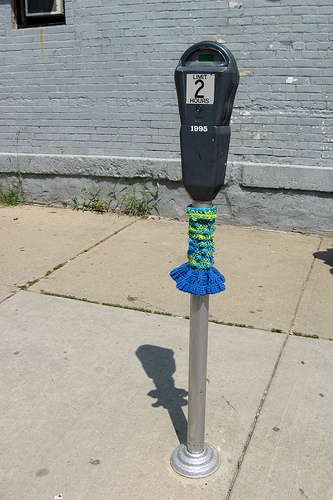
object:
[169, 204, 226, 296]
scarf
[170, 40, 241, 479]
meter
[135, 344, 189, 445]
shadow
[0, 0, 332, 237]
building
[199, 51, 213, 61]
screen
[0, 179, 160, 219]
weeds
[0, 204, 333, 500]
pavement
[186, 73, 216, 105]
sign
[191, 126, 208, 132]
number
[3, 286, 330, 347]
line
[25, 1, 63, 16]
air conditioner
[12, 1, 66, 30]
window